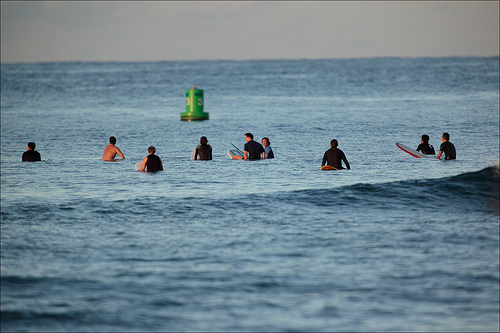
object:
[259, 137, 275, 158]
woman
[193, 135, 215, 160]
man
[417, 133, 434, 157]
man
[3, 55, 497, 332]
ocean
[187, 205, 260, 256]
ripples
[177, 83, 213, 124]
buoy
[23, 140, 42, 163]
man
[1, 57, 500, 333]
water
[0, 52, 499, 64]
horizon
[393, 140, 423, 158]
surfboard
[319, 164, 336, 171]
surfboard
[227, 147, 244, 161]
surfboard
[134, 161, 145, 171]
surfboard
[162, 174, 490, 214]
wave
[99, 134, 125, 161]
man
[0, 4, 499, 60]
sky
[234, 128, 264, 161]
person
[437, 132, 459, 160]
person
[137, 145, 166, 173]
person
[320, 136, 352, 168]
person